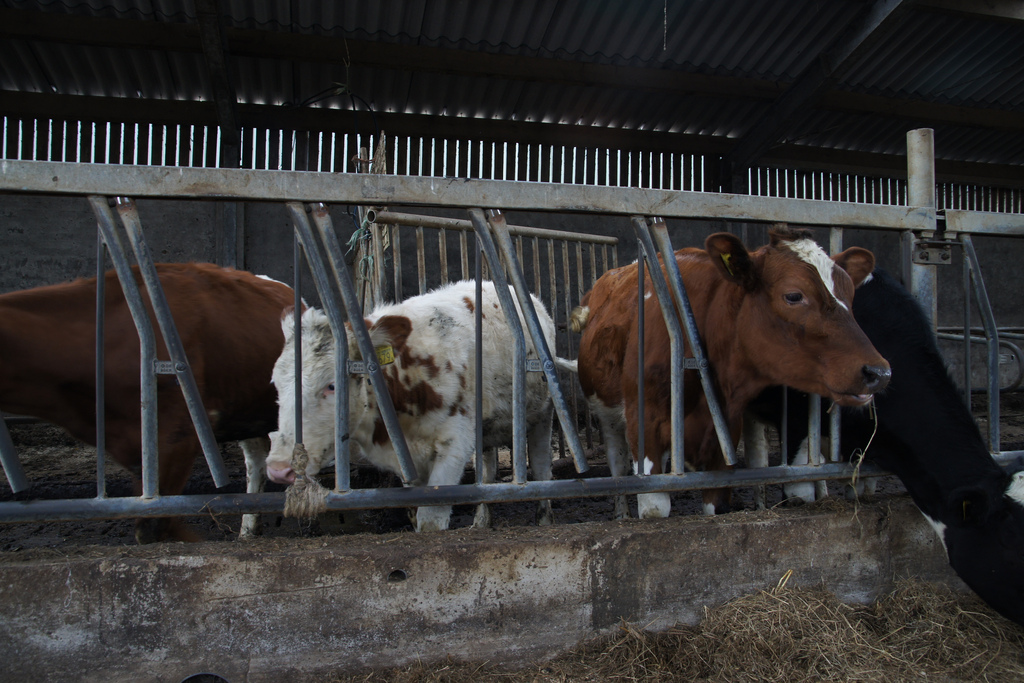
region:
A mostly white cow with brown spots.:
[264, 277, 556, 534]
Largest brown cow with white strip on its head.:
[573, 229, 893, 517]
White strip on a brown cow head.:
[781, 232, 849, 312]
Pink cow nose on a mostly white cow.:
[264, 456, 296, 486]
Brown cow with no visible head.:
[0, 260, 313, 540]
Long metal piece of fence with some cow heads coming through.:
[0, 154, 1022, 521]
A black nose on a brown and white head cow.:
[858, 359, 893, 401]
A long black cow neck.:
[852, 279, 1004, 533]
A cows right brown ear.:
[706, 232, 758, 290]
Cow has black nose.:
[857, 354, 899, 396]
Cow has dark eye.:
[783, 284, 815, 310]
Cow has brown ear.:
[694, 228, 764, 290]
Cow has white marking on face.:
[786, 228, 850, 298]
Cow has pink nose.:
[264, 454, 299, 484]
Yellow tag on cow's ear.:
[375, 332, 415, 380]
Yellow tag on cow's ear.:
[708, 241, 738, 281]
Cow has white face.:
[258, 319, 361, 452]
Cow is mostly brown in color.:
[596, 228, 865, 473]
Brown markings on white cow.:
[369, 315, 458, 464]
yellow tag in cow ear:
[373, 341, 399, 365]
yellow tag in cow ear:
[711, 239, 735, 269]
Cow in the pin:
[258, 250, 579, 527]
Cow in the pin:
[563, 214, 886, 459]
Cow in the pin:
[8, 250, 331, 527]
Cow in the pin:
[855, 253, 1023, 607]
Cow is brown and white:
[250, 252, 582, 508]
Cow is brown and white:
[566, 211, 906, 499]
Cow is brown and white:
[3, 243, 321, 550]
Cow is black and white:
[846, 252, 1021, 657]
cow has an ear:
[704, 232, 752, 283]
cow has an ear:
[366, 314, 411, 366]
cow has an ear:
[279, 298, 311, 337]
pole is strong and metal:
[467, 208, 586, 474]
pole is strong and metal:
[652, 210, 736, 466]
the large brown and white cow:
[266, 275, 560, 538]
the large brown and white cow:
[5, 257, 304, 510]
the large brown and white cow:
[563, 215, 886, 517]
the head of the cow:
[273, 309, 356, 477]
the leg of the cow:
[413, 407, 486, 544]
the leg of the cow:
[526, 396, 556, 517]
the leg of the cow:
[466, 417, 504, 525]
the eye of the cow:
[314, 379, 335, 395]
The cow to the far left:
[5, 237, 312, 490]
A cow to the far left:
[5, 238, 309, 491]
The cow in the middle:
[267, 231, 575, 466]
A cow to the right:
[567, 216, 884, 454]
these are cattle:
[135, 180, 895, 544]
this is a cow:
[201, 285, 559, 599]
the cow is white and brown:
[230, 276, 541, 511]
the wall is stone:
[63, 326, 449, 658]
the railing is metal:
[244, 159, 619, 477]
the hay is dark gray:
[663, 570, 897, 670]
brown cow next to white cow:
[1, 258, 316, 542]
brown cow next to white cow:
[574, 226, 895, 518]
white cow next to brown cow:
[266, 282, 578, 531]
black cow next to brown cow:
[738, 271, 1021, 622]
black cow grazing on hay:
[728, 272, 1022, 626]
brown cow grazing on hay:
[561, 232, 893, 519]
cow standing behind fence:
[2, 258, 305, 530]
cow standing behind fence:
[263, 278, 580, 530]